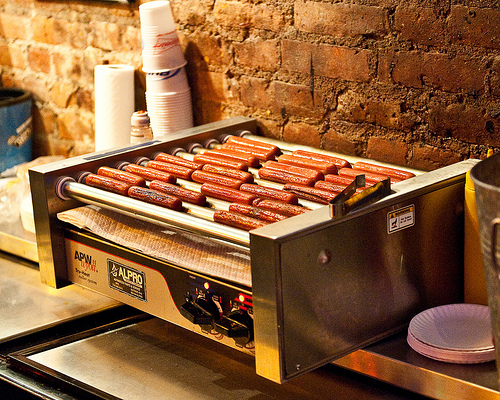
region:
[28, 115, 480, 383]
cooked hotdogs on a silver metal hotdog grill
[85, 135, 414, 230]
metal tongs to the right of the cooking hotdogs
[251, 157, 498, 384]
stack of small white paper plates near the right side of the grill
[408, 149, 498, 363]
yellow plastic mustard dispenser is behind the paper plates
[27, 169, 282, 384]
black and white logo sticker on the front of the grill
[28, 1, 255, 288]
stack of white plastic cups near the left side of the grill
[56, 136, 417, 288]
greasy paper towel is under the cooking hotdogs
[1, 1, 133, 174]
blue plastic big gulp cup is to the left of the paper towels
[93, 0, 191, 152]
white half used roll of paper towels is to the left of the cups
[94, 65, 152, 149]
top of ketchup bottle to the right of the paper towels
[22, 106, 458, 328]
several hotdogs on a oven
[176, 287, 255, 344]
control knobs for a oven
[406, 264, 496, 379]
a stack of paper plates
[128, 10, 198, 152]
a stack of plastic cups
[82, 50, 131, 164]
a roll of paper towels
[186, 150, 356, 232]
several hotdogs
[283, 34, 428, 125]
a brick wall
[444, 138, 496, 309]
a mustard container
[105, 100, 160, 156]
top of a ketchup bottle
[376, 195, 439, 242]
a safety sticker on the side of oven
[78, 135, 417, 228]
Hot dogs on a grill.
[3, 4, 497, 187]
Brick wall behind hot dogs.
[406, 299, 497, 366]
White paper plates.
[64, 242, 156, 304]
Brand of griller for hot dogs.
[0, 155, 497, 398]
Metal countertop in area.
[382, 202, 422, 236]
Caution sign for machine.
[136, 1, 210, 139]
Plastic cups stacked up.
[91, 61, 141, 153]
Paper towels on counter.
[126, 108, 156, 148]
Top of ketchup bottle.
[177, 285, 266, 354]
Knobs for grilling hot dogs.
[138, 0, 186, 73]
white plastic cup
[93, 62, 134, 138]
Paper towel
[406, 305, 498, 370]
White paper plates on counter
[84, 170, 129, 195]
Hot dog on a roller grill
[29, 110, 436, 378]
Hot dog roller grill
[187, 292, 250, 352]
Control knobs for roller grill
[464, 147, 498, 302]
Yellow mustard dispenser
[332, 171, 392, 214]
Metal tongs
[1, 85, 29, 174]
Blue and black bucket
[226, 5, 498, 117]
Brick wall behind roller grill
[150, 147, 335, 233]
Hot dogs cooking on electric grill.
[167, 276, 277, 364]
Control knobs on front of electrical grill.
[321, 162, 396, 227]
Tongs used to turn hot dogs on grill.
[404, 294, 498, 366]
Plates sitting next to grill.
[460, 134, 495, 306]
Tall bottle of mustard sitting next to grill.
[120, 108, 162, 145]
Top of bottle of ketchup sitting next to grill.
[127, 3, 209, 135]
Stack of plastic cups turned down next to grill.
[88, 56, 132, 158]
White roll of towel paper next to grill.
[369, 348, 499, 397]
Edge of counter grill is sitting on.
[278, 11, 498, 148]
Red brick wall behind electric grill.